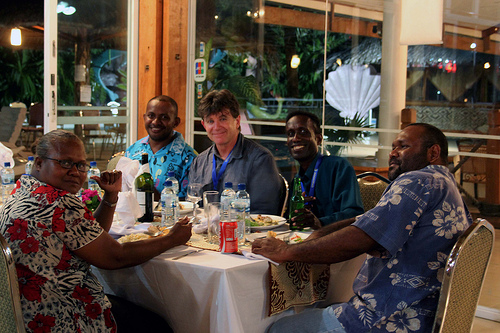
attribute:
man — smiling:
[284, 107, 369, 234]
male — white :
[194, 93, 290, 203]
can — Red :
[216, 220, 234, 255]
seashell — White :
[320, 61, 388, 118]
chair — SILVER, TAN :
[430, 218, 495, 331]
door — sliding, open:
[2, 2, 138, 139]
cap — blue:
[223, 180, 230, 188]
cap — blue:
[235, 179, 248, 191]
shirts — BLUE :
[116, 139, 467, 258]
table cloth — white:
[186, 270, 234, 300]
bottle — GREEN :
[133, 152, 159, 222]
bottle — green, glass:
[136, 155, 153, 222]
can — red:
[219, 218, 236, 253]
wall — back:
[1, 6, 497, 131]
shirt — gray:
[184, 139, 276, 213]